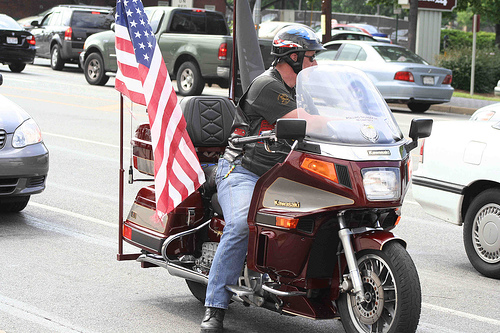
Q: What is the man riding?
A: A motorcycle.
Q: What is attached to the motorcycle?
A: An American flag.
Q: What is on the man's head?
A: A helmet.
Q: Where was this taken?
A: A busy street.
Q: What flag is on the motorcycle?
A: American flag.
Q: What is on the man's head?
A: Motorcycle helmet.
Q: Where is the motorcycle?
A: In traffic.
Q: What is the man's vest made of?
A: Leather.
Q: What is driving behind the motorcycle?
A: A car.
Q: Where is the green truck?
A: On the opposite side of the road.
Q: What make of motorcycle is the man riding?
A: Kawasaki.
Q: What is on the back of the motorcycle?
A: An American flag.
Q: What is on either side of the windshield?
A: Rearview mirrors.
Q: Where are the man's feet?
A: Touching the pavement.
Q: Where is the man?
A: On motorcycle.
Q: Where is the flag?
A: On motorcycle.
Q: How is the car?
A: Parked.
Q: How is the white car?
A: Driving.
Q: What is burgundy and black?
A: Motorcycle.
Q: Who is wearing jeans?
A: A man.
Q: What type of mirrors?
A: Side view.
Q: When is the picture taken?
A: Daytime.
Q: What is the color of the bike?
A: Red.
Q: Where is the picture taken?
A: On the road.